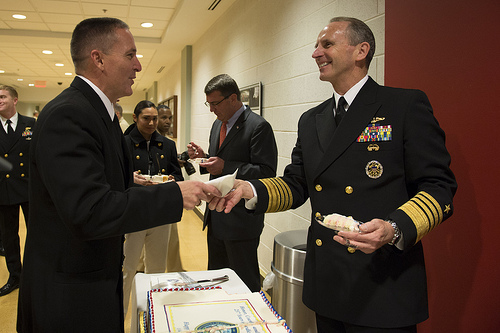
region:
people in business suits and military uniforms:
[3, 5, 489, 325]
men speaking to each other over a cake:
[15, 15, 455, 326]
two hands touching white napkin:
[172, 165, 254, 215]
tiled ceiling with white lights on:
[0, 0, 180, 96]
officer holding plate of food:
[121, 96, 176, 266]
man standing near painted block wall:
[187, 1, 297, 263]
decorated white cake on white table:
[125, 266, 290, 326]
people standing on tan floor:
[0, 196, 210, 326]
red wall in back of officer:
[310, 1, 491, 323]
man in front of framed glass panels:
[155, 90, 177, 140]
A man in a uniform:
[208, 17, 454, 328]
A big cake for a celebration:
[141, 278, 292, 331]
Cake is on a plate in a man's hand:
[317, 213, 400, 253]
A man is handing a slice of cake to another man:
[16, 15, 456, 331]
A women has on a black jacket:
[123, 99, 184, 271]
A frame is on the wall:
[241, 83, 266, 115]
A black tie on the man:
[332, 95, 349, 124]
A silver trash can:
[271, 225, 318, 332]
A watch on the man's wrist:
[389, 220, 401, 246]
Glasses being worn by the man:
[203, 96, 226, 108]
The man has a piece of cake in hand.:
[317, 188, 375, 247]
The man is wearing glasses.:
[185, 96, 236, 106]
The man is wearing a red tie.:
[198, 123, 253, 145]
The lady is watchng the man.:
[133, 93, 198, 245]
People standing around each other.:
[48, 0, 409, 313]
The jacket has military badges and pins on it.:
[333, 120, 405, 202]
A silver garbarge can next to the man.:
[261, 191, 318, 326]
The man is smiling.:
[311, 43, 380, 145]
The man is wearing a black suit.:
[35, 81, 149, 293]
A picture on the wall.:
[216, 63, 281, 120]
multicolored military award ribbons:
[353, 124, 393, 141]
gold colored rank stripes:
[396, 190, 445, 247]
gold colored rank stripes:
[258, 176, 293, 211]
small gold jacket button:
[343, 185, 355, 193]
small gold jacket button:
[313, 182, 320, 189]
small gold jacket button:
[313, 210, 320, 218]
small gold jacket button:
[314, 238, 323, 248]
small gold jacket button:
[348, 245, 356, 254]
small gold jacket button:
[18, 151, 23, 156]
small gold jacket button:
[17, 161, 24, 166]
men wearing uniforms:
[8, 3, 493, 287]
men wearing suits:
[27, 3, 490, 296]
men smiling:
[19, 9, 483, 329]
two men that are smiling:
[8, 15, 463, 330]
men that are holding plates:
[15, 10, 491, 330]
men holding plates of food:
[25, 6, 495, 312]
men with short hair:
[20, 6, 470, 302]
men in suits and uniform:
[15, 7, 433, 308]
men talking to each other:
[5, 10, 492, 281]